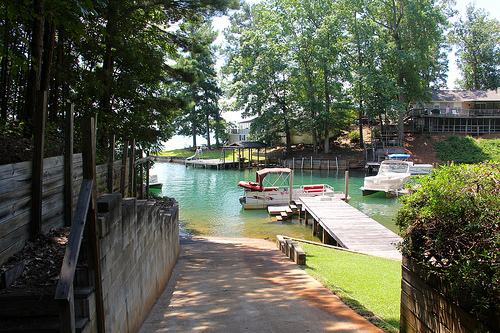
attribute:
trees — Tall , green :
[222, 19, 372, 144]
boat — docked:
[237, 164, 350, 208]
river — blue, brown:
[156, 158, 428, 255]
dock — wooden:
[296, 192, 410, 262]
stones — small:
[260, 226, 324, 276]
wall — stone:
[73, 194, 198, 331]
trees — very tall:
[191, 0, 198, 152]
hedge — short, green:
[397, 138, 499, 308]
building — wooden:
[395, 75, 495, 137]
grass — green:
[288, 237, 417, 331]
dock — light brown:
[286, 180, 372, 271]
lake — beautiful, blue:
[111, 147, 422, 244]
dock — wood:
[298, 197, 448, 265]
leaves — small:
[453, 182, 493, 240]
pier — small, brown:
[309, 210, 376, 239]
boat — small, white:
[234, 160, 354, 213]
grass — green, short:
[287, 232, 428, 327]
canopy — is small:
[250, 162, 297, 191]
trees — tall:
[253, 21, 461, 172]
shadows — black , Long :
[109, 212, 362, 329]